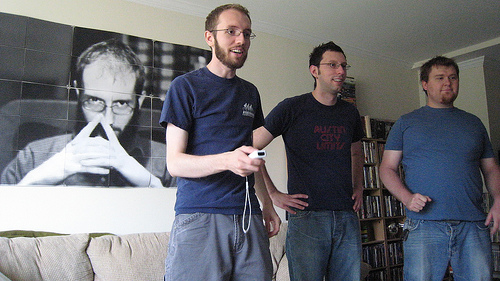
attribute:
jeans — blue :
[392, 207, 488, 278]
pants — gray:
[164, 209, 273, 278]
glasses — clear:
[206, 22, 254, 41]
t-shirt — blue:
[164, 66, 261, 218]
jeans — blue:
[286, 202, 364, 276]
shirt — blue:
[383, 103, 493, 226]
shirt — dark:
[259, 86, 369, 213]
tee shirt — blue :
[263, 90, 373, 217]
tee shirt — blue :
[160, 64, 270, 214]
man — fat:
[162, 7, 280, 279]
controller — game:
[239, 148, 270, 162]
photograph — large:
[0, 12, 212, 185]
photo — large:
[2, 13, 217, 199]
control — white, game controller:
[238, 146, 268, 175]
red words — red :
[308, 122, 348, 157]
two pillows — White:
[0, 232, 171, 279]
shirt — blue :
[167, 68, 274, 223]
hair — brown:
[203, 4, 256, 26]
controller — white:
[231, 147, 276, 236]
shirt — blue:
[164, 68, 272, 212]